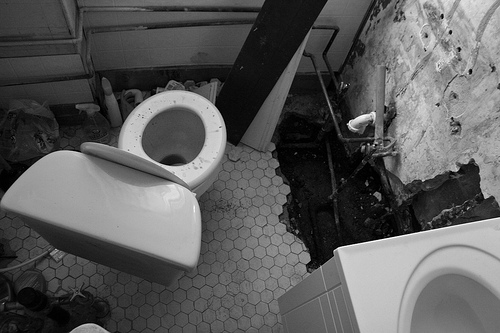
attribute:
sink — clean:
[338, 214, 500, 331]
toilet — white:
[4, 87, 234, 280]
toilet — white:
[120, 71, 280, 225]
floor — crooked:
[206, 125, 345, 309]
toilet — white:
[16, 79, 243, 287]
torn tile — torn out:
[278, 86, 388, 264]